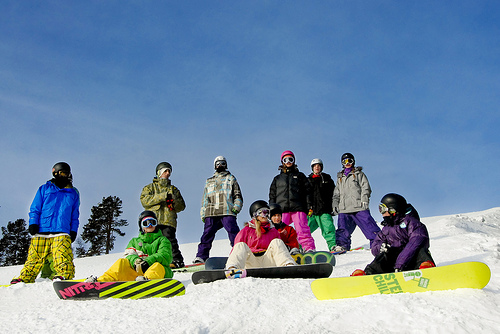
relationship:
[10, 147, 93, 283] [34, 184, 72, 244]
man in blue jacket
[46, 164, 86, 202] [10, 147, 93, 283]
black mask on man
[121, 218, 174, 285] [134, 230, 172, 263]
man in green jacket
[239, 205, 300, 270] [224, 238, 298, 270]
girl in snow pants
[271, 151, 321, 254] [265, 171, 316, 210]
woman in black jacket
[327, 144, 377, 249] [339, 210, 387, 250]
female in purple pants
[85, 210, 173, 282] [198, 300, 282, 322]
man sitting in snow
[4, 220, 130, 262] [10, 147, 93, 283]
trees behind man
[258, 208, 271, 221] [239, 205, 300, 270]
goggled on girl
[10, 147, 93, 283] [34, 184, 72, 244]
man wearing blue jacket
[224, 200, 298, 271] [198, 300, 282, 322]
girl sitting in snow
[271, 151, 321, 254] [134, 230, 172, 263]
woman wearing green jacket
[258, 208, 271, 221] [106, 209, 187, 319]
goggled on person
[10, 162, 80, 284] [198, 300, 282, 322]
man standing in snow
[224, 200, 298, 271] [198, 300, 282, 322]
girl in snow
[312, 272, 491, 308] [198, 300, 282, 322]
snowboard in snow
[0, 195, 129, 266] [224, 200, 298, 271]
trees behind girl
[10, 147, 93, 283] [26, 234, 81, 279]
man wearing yellow pants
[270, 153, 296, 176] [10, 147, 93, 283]
helmet on man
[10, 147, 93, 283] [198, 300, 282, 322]
man standing in snow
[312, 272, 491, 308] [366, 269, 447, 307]
snowboard has design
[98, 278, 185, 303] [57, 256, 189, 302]
stripes on snowboard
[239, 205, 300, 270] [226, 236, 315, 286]
girl in snow pants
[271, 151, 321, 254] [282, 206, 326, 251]
woman in pink pants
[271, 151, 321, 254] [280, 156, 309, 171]
woman wearing blue goggles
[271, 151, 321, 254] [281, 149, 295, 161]
woman in helmet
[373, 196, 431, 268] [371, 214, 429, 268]
gal in jacket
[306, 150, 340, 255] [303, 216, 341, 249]
dude in green snow pants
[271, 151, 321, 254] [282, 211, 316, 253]
woman wearing pants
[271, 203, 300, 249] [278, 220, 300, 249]
person in red coat